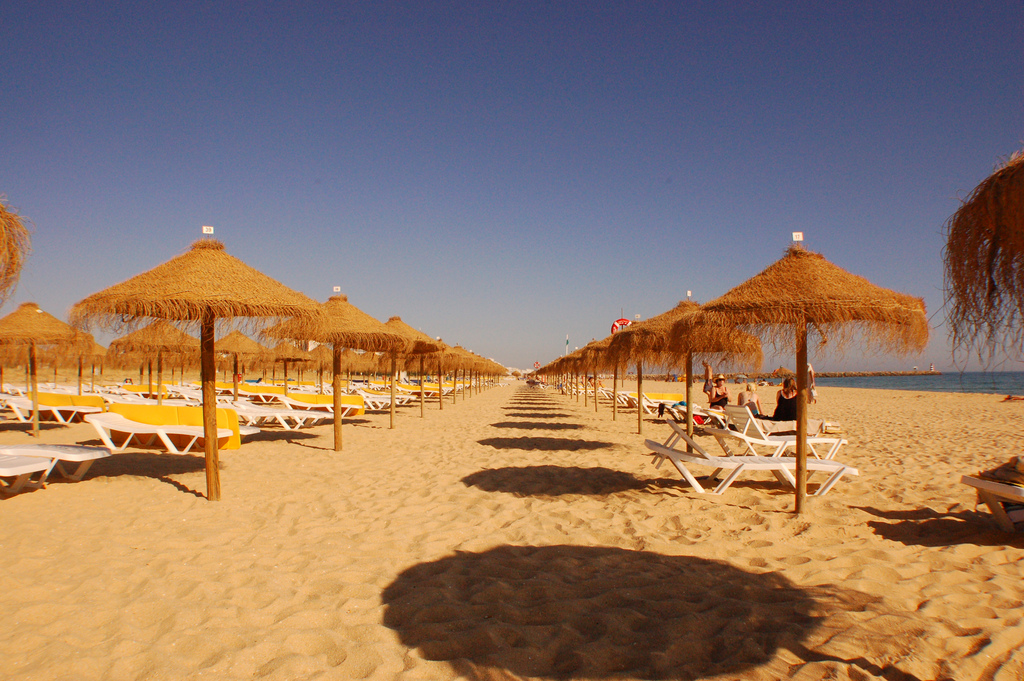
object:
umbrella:
[257, 286, 414, 452]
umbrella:
[384, 315, 446, 429]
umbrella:
[666, 231, 930, 514]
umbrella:
[608, 290, 761, 453]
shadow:
[380, 543, 919, 681]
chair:
[83, 411, 234, 450]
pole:
[200, 305, 221, 501]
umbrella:
[68, 226, 327, 502]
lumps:
[787, 603, 931, 680]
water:
[706, 367, 1024, 395]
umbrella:
[680, 231, 927, 357]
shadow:
[459, 465, 821, 514]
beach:
[0, 369, 1022, 679]